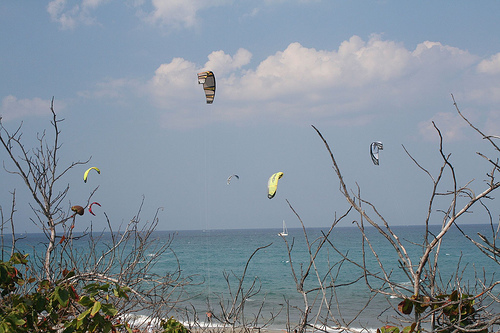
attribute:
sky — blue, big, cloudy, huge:
[1, 1, 499, 216]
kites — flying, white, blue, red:
[60, 55, 313, 222]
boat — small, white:
[274, 215, 295, 245]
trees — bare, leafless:
[0, 111, 500, 323]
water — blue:
[1, 229, 499, 325]